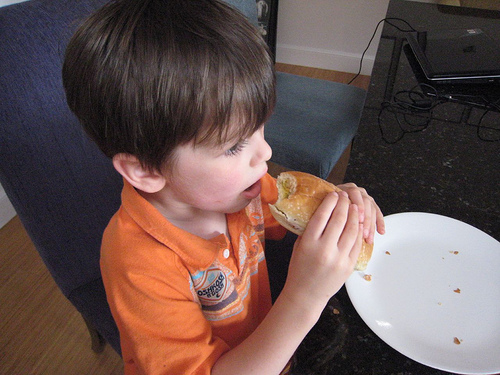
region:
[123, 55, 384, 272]
The little boy is eating a sandwich.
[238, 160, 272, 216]
The boy mouth is open.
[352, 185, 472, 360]
A white plate on the table.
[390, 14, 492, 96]
A black laptop sitting on the table.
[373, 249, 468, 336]
Bread crumbs on the white plate.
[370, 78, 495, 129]
Black cords hanging from the laptop.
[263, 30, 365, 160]
A blue chair next to the table.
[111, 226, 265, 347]
The shirt is orange.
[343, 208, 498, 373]
white plate on table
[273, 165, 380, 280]
hoagy sandwich in brown bread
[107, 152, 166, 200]
ear of a child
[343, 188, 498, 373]
white plate with crumbs on it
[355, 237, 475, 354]
crumbs on top of white plate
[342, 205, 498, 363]
round white plate on table top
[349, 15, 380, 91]
cord hanging off table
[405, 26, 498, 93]
laptop on edge of counter top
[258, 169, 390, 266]
boy is eating a sandwich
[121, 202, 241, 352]
boy is wearing an orange shirt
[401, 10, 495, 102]
netbook closed on the table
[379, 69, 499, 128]
netbook cords on the table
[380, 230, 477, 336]
crumbs on the plate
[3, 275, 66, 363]
floor is made of wood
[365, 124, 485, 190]
black table top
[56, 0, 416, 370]
A child eating a sandwich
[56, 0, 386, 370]
A child eating a sandwich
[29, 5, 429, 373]
A boy eating a sandwich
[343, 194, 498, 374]
A white plate with crumbs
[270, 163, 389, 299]
A boy's hands holding a sandwich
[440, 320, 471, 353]
A brown crumb on a plate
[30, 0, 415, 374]
A boy wearing an orange shirt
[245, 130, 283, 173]
A little boy's nose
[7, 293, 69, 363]
A brown hardwood floor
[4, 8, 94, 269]
The back of a purple chair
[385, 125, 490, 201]
A black granite countertop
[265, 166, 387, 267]
a sandwhich in a boys hands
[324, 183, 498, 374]
an empty white plate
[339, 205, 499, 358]
empty plate with crumbs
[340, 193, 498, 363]
empty plate with crumbs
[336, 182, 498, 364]
empty plate with crumbs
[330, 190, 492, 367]
empty plate with crumbs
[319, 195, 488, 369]
empty plate with crumbs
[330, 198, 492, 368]
empty plate with crumbs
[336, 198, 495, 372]
empty plate with crumbs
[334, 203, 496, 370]
empty plate with crumbs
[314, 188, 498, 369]
empty plate with crumbs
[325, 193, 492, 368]
empty plate with crumbs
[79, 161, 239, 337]
child wearing orange shirt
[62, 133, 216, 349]
child sitting on a chair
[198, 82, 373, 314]
child sitting eating a sandwich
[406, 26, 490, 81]
off laptop on the table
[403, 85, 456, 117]
black wires on the table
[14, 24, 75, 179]
padded chair with blue lining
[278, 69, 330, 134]
padded chair with blue lining